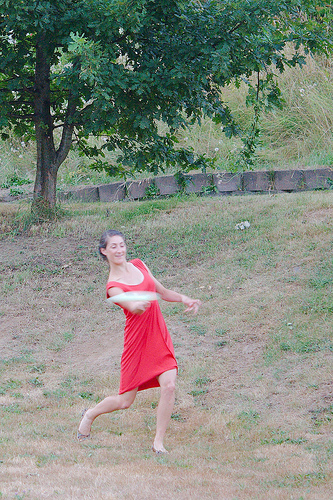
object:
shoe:
[76, 411, 92, 441]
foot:
[77, 406, 94, 443]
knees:
[114, 393, 133, 411]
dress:
[104, 257, 179, 394]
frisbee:
[108, 291, 159, 305]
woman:
[77, 230, 205, 455]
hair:
[98, 227, 124, 259]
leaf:
[235, 219, 251, 231]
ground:
[0, 194, 333, 499]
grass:
[0, 186, 332, 498]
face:
[106, 239, 127, 264]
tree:
[0, 0, 332, 220]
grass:
[0, 0, 332, 195]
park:
[0, 0, 333, 498]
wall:
[57, 170, 332, 205]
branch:
[57, 22, 225, 164]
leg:
[153, 369, 175, 439]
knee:
[159, 379, 177, 394]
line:
[131, 303, 154, 388]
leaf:
[68, 30, 88, 52]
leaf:
[133, 113, 151, 130]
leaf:
[261, 40, 277, 52]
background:
[0, 0, 333, 210]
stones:
[306, 163, 332, 191]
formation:
[61, 164, 332, 202]